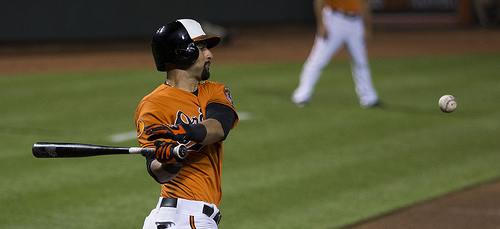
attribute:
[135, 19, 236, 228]
man — hitting, swinging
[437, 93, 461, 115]
ball — traveling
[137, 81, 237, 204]
uniform — orange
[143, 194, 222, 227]
pants — white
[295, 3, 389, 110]
man — walking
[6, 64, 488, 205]
grass — green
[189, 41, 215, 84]
face — serious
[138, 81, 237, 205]
shirt — black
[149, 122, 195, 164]
gloves — orange, black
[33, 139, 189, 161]
bat — swinging